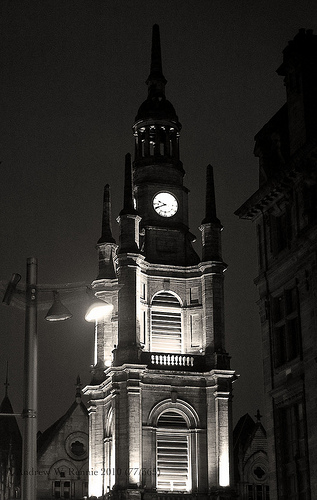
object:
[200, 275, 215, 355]
column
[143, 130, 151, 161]
column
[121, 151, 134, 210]
column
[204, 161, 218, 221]
column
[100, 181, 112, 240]
column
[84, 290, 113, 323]
light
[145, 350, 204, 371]
railing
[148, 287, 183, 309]
window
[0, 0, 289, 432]
sky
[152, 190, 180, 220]
light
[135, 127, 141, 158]
column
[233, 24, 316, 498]
building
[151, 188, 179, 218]
clock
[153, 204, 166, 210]
hand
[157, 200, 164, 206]
hand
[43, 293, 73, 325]
light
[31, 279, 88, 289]
line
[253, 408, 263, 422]
cross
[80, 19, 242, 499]
tower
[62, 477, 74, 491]
window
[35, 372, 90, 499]
building